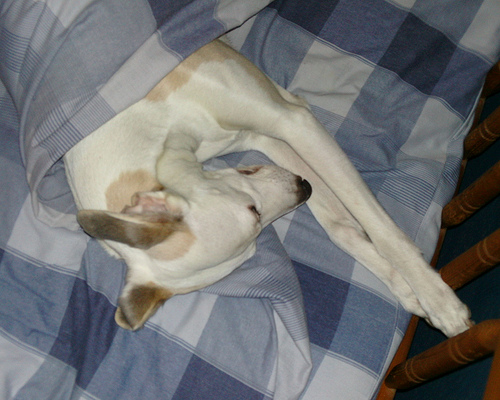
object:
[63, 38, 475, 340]
dog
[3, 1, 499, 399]
bed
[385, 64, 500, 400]
railing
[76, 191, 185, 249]
ear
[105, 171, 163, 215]
spot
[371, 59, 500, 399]
headboard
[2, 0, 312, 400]
sheet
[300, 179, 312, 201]
nose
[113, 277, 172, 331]
ear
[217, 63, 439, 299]
front leg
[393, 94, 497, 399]
carpet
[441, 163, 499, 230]
rung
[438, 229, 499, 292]
rung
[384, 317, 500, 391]
rung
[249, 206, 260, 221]
left eye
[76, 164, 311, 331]
head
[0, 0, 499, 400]
sheet